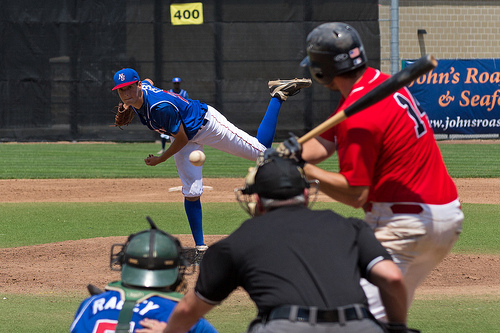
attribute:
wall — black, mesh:
[1, 2, 380, 139]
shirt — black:
[196, 203, 391, 306]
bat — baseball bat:
[297, 52, 437, 145]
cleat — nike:
[266, 78, 308, 105]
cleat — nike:
[191, 247, 207, 263]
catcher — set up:
[69, 230, 218, 330]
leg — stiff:
[172, 141, 205, 249]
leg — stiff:
[203, 77, 312, 159]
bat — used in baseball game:
[293, 51, 443, 168]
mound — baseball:
[70, 224, 492, 301]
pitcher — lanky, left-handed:
[101, 52, 314, 248]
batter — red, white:
[293, 18, 470, 325]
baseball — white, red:
[175, 144, 210, 181]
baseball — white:
[182, 147, 214, 172]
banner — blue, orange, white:
[399, 47, 496, 133]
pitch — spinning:
[108, 67, 233, 181]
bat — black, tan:
[294, 50, 441, 151]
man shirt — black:
[225, 163, 428, 330]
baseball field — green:
[2, 138, 497, 331]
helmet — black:
[299, 19, 372, 88]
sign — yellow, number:
[166, 0, 204, 25]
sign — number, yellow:
[404, 57, 498, 139]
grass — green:
[51, 137, 149, 187]